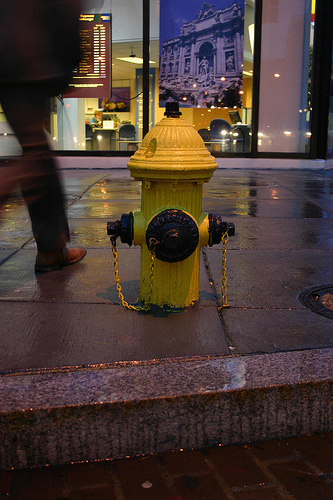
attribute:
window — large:
[45, 0, 142, 154]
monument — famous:
[162, 5, 239, 93]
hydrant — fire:
[106, 101, 235, 308]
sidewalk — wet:
[220, 169, 277, 220]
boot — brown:
[32, 224, 85, 275]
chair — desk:
[117, 124, 136, 151]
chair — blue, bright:
[209, 118, 248, 149]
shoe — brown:
[33, 246, 87, 272]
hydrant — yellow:
[101, 101, 219, 310]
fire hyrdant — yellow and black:
[86, 92, 235, 304]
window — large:
[41, 0, 257, 155]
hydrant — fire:
[88, 108, 230, 305]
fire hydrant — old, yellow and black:
[106, 102, 231, 311]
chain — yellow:
[220, 232, 229, 309]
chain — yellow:
[109, 235, 156, 311]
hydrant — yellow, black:
[116, 102, 226, 270]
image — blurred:
[10, 17, 103, 285]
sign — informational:
[83, 12, 107, 87]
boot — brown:
[33, 243, 88, 277]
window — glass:
[45, 3, 317, 147]